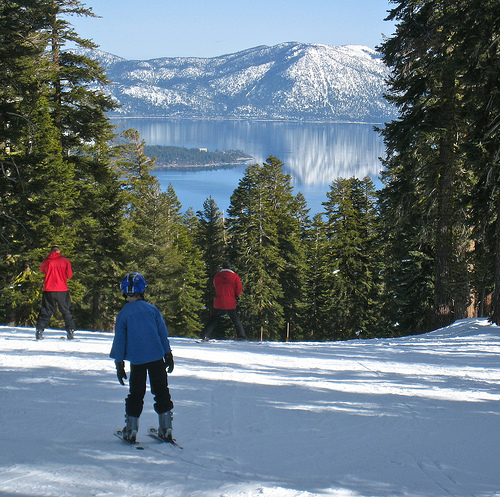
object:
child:
[108, 271, 176, 439]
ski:
[113, 429, 145, 451]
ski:
[146, 424, 185, 450]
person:
[34, 244, 76, 340]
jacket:
[39, 251, 73, 292]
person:
[199, 260, 246, 343]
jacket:
[211, 269, 243, 311]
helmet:
[119, 271, 149, 297]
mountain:
[34, 40, 430, 124]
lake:
[58, 116, 407, 226]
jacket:
[108, 300, 172, 366]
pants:
[36, 290, 76, 334]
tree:
[222, 163, 289, 341]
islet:
[90, 142, 254, 174]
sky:
[57, 0, 411, 62]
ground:
[1, 316, 499, 495]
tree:
[123, 181, 182, 338]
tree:
[315, 177, 381, 345]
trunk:
[259, 324, 264, 341]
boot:
[119, 414, 140, 445]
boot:
[157, 407, 174, 439]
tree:
[1, 0, 99, 333]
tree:
[44, 1, 128, 337]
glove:
[114, 360, 128, 387]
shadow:
[4, 347, 500, 490]